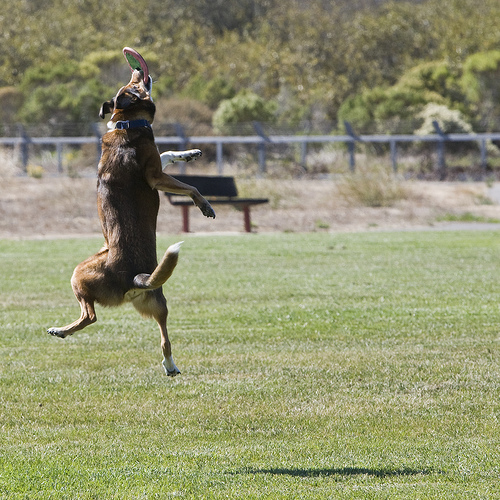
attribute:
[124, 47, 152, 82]
frisbee — red, green, pink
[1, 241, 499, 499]
grass — green, brown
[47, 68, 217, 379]
dog — brown, white, jumping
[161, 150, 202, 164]
paw — brown, white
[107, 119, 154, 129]
collar — blue, silver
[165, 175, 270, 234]
bench — wooden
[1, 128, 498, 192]
fence — tall, silver, metal, long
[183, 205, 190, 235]
post — red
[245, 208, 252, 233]
post — red